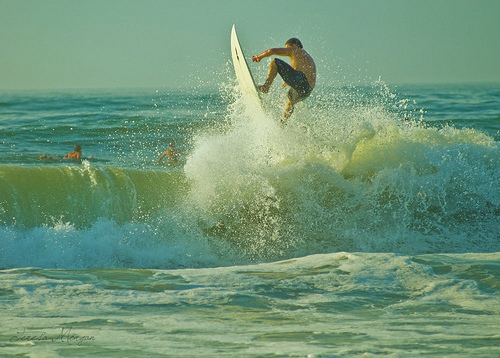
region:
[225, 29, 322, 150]
person on a surfboard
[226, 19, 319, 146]
person surfing in the ocean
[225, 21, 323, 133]
man on a surfboard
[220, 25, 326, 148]
person riding a wave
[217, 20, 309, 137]
man riding a wave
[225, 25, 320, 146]
man on white surfboard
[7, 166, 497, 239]
a wave of water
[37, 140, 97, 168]
person swimming in the distance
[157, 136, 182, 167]
partial view of person behind wave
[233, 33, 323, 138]
man is wearing black shorts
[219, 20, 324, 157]
surfer catching a wave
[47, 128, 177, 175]
people swimming behind wave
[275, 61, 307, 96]
black trunks of surfboarder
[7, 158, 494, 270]
wave crashing into ocean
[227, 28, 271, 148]
white bottom of surfboard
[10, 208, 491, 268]
white foam of wave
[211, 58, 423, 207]
white spray surfboard is kicking up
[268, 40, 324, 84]
shirtless torso of surfer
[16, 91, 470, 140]
calm waters behind wave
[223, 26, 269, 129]
surfboard coming of water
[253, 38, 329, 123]
the man on the surfboard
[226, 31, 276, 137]
the surf board the man is using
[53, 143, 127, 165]
the surfer laying on his board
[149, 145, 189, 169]
the other person out in the ocean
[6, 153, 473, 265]
the big surfing wave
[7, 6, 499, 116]
the blue sky in the background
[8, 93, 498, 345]
the water in the ocean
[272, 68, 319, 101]
the surfer's blue shorts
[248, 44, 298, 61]
the surfer's visible arm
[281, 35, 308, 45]
the surfer up in the air's hair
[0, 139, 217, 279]
rolling wave with light green color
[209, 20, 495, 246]
foamy wave with surf boarder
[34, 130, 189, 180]
two surfers laying on their surf boards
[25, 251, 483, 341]
foamy surface of water on the ocean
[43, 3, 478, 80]
light blue sky over the ocean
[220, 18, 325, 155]
black shorts on a surfer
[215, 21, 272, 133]
white surf board pointing at the sky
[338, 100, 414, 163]
sunlight reflected through a foamy wave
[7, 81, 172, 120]
waves far out in the ocean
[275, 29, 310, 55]
head of surfer with black hair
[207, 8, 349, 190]
Man riding on a surfboard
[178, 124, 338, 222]
White wave over water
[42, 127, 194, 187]
People swimming in background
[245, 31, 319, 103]
Man in blue swimsuit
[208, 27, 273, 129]
White surfboard in water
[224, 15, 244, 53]
Point of a surfboard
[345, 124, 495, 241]
Large wave in water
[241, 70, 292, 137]
Barefoot near a surfboard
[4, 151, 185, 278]
Rolling wave in an ocean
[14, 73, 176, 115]
Horizon where sky meets water